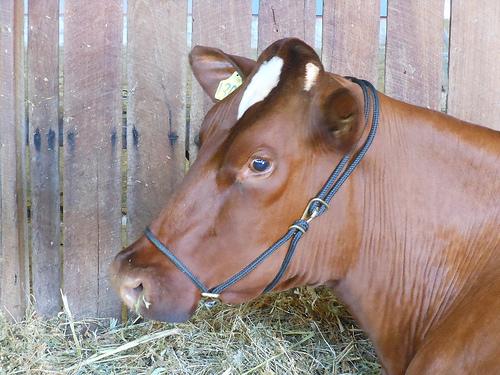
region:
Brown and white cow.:
[104, 39, 499, 373]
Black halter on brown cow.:
[108, 35, 387, 335]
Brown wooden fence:
[3, 6, 497, 314]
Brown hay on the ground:
[3, 306, 353, 374]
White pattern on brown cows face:
[229, 50, 288, 132]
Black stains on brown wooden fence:
[10, 115, 182, 160]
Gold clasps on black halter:
[279, 201, 336, 239]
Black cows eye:
[237, 143, 279, 196]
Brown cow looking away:
[101, 39, 499, 369]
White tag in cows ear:
[215, 61, 247, 110]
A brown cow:
[124, 73, 497, 338]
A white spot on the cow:
[236, 52, 316, 120]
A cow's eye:
[247, 141, 284, 183]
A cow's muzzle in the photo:
[102, 247, 164, 321]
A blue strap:
[287, 173, 348, 226]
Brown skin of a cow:
[388, 134, 447, 279]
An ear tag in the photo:
[210, 69, 245, 101]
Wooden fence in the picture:
[61, 68, 179, 187]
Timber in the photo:
[60, 50, 130, 210]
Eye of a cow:
[244, 154, 273, 177]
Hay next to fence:
[0, 279, 385, 374]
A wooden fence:
[0, 1, 499, 339]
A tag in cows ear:
[213, 70, 240, 100]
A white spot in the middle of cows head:
[233, 54, 284, 121]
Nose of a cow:
[107, 249, 164, 309]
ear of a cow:
[186, 44, 252, 104]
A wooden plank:
[63, 1, 123, 331]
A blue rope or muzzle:
[142, 76, 378, 306]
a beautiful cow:
[111, 24, 457, 365]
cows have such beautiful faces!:
[95, 34, 467, 346]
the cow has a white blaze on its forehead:
[228, 48, 290, 137]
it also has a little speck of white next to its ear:
[297, 53, 328, 97]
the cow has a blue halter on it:
[110, 62, 385, 327]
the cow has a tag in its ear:
[205, 69, 247, 104]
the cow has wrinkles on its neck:
[179, 44, 477, 352]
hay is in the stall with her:
[66, 330, 359, 373]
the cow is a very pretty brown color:
[101, 45, 499, 349]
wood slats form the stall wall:
[13, 42, 172, 177]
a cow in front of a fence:
[92, 26, 497, 369]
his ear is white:
[239, 48, 281, 115]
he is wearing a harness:
[98, 49, 385, 326]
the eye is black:
[253, 150, 275, 176]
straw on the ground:
[2, 273, 414, 373]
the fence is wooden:
[2, 0, 497, 325]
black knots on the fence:
[26, 126, 184, 153]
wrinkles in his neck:
[315, 140, 497, 347]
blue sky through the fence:
[246, 0, 260, 14]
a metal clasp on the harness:
[280, 192, 334, 239]